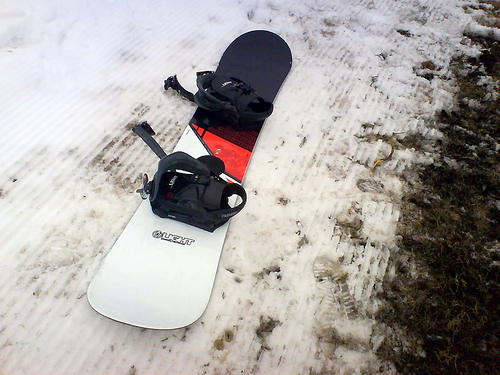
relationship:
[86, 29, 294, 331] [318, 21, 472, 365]
snow board on ground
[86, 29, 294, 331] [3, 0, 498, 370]
snow board on ground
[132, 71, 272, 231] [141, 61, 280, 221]
places fit feet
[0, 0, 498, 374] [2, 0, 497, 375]
grass next snow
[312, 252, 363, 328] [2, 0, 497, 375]
footprint on snow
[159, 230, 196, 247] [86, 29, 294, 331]
light on snow board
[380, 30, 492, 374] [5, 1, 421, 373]
grass next snow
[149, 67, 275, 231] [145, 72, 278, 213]
feet place has place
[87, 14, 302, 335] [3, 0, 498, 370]
snow board on ground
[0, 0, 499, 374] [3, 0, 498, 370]
snow on ground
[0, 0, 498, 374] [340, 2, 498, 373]
grass on ground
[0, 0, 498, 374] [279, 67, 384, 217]
grass on ground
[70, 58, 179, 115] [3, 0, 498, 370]
snow on ground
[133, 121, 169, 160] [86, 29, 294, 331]
straps on snow board